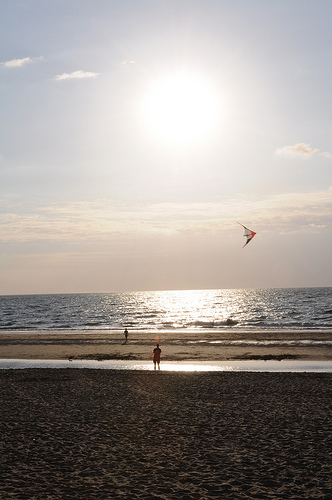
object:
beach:
[0, 328, 330, 499]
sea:
[0, 286, 331, 332]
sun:
[142, 74, 218, 155]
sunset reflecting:
[113, 289, 281, 338]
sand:
[0, 334, 331, 499]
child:
[121, 327, 128, 341]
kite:
[237, 221, 258, 250]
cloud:
[271, 143, 329, 161]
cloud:
[0, 53, 34, 73]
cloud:
[53, 68, 99, 83]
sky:
[0, 0, 331, 295]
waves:
[0, 286, 58, 327]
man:
[151, 342, 162, 371]